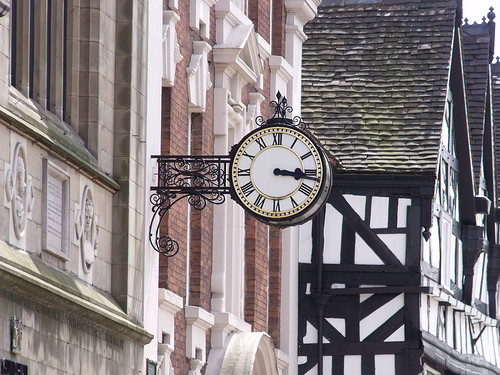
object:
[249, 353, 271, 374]
doorway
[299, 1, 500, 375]
building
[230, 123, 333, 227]
clock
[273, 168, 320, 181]
hands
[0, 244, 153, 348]
stone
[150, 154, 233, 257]
post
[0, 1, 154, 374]
building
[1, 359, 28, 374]
black tiles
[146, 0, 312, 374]
building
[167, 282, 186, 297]
red brick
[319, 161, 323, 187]
gold border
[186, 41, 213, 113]
details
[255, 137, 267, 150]
roman numbers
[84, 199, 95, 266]
portrait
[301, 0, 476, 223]
roof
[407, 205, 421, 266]
wood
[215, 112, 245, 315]
window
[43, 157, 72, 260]
plaque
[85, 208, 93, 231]
face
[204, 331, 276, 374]
archway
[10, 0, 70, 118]
windows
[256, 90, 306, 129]
decorations